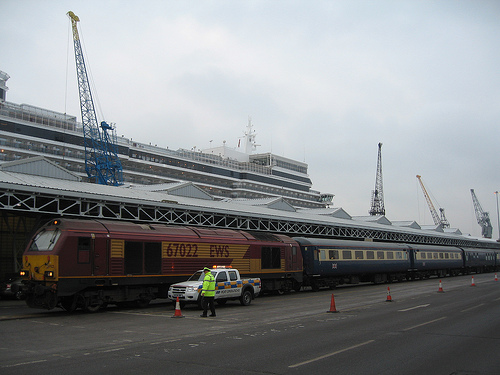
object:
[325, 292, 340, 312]
cone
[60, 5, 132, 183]
crane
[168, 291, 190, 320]
cone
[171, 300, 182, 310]
stripe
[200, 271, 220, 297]
jacket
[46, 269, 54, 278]
headlights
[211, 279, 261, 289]
checkers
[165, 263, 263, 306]
truck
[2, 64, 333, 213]
boat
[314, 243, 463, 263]
stripe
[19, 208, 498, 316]
train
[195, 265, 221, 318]
man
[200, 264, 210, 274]
hat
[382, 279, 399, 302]
cone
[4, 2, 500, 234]
sky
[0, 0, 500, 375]
scene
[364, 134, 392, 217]
canes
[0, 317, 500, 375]
road